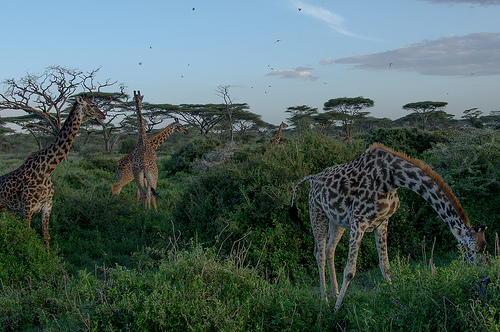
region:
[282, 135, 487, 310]
The giraffe bending to eat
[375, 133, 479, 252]
The long neck of the nearest giraffe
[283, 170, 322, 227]
The tail of the nearest giraffe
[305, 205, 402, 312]
The legs of the nearest giraffe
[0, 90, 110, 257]
The giraffe furthest to the left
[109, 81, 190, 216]
The two giraffes standing next to each other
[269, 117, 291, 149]
The giraffe with only neck and head visible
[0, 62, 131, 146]
The tree without any leaves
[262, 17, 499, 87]
Clouds in the sky on the right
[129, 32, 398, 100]
The birds flying in the air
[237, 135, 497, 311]
THE GIRAFFE IS GRAZING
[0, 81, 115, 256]
THE GIRAFFE IS STANDING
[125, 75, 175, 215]
THE GIRAFFE HAS IT'S BACK TURNED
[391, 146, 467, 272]
THE GIRAFFE HAS A LONG NECK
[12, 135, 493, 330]
THE GRASS AND BUSHES SURROUND THE GIRAFFES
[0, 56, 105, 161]
THE TREE HAS NO LEAVES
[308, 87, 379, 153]
THE TREE IS TALL AND IN THE BACKGROUND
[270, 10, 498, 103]
THESE CLOUDS ARE FLUFFY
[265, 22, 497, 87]
THIS CLOUD IS VERY LARGE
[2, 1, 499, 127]
THIS IS A CLOUDY BLUE SKY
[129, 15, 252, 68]
Pale blue sky in the distance.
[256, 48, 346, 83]
Puffy white clouds in the sky.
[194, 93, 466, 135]
Tall trees on the horizon.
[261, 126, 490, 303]
Giraffe grazing in the bush.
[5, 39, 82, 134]
A tree bare of leaves.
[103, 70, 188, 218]
Two giraffe's standing together.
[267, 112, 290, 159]
A giraffe not with the others.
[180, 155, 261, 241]
Lush green foliage for the giraffe's to eat.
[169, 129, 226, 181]
Small green tree in the distance.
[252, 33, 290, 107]
Flock of birds flying in the sky.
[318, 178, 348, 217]
part of a tummy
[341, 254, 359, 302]
part of a knee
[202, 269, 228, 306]
part of a plant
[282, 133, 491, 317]
The giraffe bending down to eat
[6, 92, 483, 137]
The tall shade trees in the background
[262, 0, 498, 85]
The clouds in the sky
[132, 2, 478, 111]
The birds flying in the air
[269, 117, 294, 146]
Giraffe who only has its head and neck visible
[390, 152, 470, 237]
The neck of the nearest giraffe